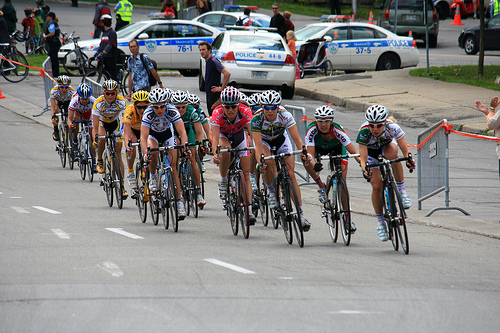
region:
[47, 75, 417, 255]
Cyclists in a race.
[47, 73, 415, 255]
All of the women are wearing helmets.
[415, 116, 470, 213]
A broken metal barricade.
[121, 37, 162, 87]
A man wearing a backpack.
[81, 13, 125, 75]
A man standing with a bicycle.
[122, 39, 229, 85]
Two men watching the race.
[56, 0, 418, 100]
Several parked police cars.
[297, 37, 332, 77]
A stroller for a child.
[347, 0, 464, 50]
Orange traffic cones around an SUV.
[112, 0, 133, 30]
An officer wearing a yellow vest.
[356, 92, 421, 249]
racer on bicycle on road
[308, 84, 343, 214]
racer on bicycle on road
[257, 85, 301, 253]
racer on bicycle on road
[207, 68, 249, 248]
racer on bicycle on road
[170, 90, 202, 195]
racer on bicycle on road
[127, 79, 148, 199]
racer on bicycle on road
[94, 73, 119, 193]
racer on bicycle on road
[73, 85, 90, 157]
racer on bicycle on road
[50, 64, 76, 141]
racer on bicycle on road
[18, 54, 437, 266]
bicyclists riding on the road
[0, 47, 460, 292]
many bicyclists riding on the road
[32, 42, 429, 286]
multiple bicyclists riding on the road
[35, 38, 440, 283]
alert bicyclists riding on the road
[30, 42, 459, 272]
energetic bicyclists riding on the road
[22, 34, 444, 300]
some bicyclists riding the roadway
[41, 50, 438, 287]
several bicyclists riding the roadway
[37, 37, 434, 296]
multiple bicyclists riding the roadway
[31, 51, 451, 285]
alert bicyclists riding the roadway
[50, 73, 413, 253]
group of bicyclists on the road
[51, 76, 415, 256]
several cyclists in a line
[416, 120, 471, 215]
metal barrier in the street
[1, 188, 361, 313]
white lines on the road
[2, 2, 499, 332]
paved road with people, bikes, and cars on it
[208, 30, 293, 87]
back of police car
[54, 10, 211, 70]
parked police cruiser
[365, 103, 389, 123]
white bicycle helmet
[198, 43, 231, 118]
man standing and watching bikers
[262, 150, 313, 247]
bicycle in motion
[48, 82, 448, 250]
bicylists in a race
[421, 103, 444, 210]
barricade in the street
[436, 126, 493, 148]
orange tape on the barricade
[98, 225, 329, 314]
white markings on the road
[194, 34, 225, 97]
man with hands on hips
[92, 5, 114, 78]
person looking over shoulder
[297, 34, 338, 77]
carriage on the corner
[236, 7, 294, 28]
people behind the car